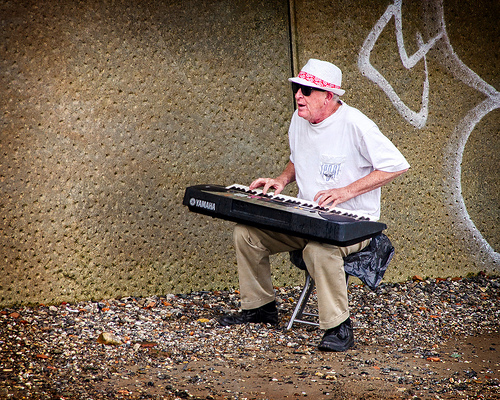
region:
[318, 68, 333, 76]
man wearing white hat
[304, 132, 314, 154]
man wearing white shirt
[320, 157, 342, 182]
blue design on shirt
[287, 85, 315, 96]
man wearing black sunglasses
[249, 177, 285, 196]
man left hand on keyboard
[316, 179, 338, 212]
man right hand on keyboard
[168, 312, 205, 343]
rocks and glass on ground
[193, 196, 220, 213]
white lettering on keyboard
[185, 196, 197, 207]
circle symbol on board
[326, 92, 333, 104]
red hearing aid in ear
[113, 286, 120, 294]
dent in brown wall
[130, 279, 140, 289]
dent in brown wall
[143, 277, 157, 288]
dent in brown wall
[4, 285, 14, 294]
dent in brown wall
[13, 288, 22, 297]
dent in brown wall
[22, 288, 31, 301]
dent in brown wall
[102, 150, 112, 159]
dent in brown wall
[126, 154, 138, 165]
dent in brown wall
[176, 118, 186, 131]
dent in brown wall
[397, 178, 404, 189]
dent in brown wall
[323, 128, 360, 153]
a white shirt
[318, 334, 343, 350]
a black shoe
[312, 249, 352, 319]
man is wearing brown pants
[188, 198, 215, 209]
brand of the piano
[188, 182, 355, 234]
a piano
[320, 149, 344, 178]
a pocket on the shirt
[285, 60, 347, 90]
a white hat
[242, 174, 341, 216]
the man is playing the piano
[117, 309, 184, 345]
particles on the ground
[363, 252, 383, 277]
a black plastic bag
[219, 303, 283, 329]
Foot of keyboard player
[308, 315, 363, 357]
Foot of keyboard player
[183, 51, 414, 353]
Elderly Man playing keyboard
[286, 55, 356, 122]
Head of man playing keyboard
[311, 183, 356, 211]
Hand of man playing keyboard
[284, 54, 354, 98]
Hatof man playing keyboard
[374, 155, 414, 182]
Elbow of man playing keyboard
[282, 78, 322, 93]
Sunglasses of many playing keyboard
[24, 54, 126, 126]
Part of wall behind man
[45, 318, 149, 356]
Part of pebbles on ground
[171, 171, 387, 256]
a piano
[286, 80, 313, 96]
man is wearing sunglasses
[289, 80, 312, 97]
black sunglasses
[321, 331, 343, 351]
the man is wearing black shoes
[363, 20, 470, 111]
tagging on the wall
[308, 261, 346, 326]
man is wearing brown pants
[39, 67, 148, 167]
the wall is brown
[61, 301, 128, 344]
particels on the ground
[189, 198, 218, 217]
brand on the piano